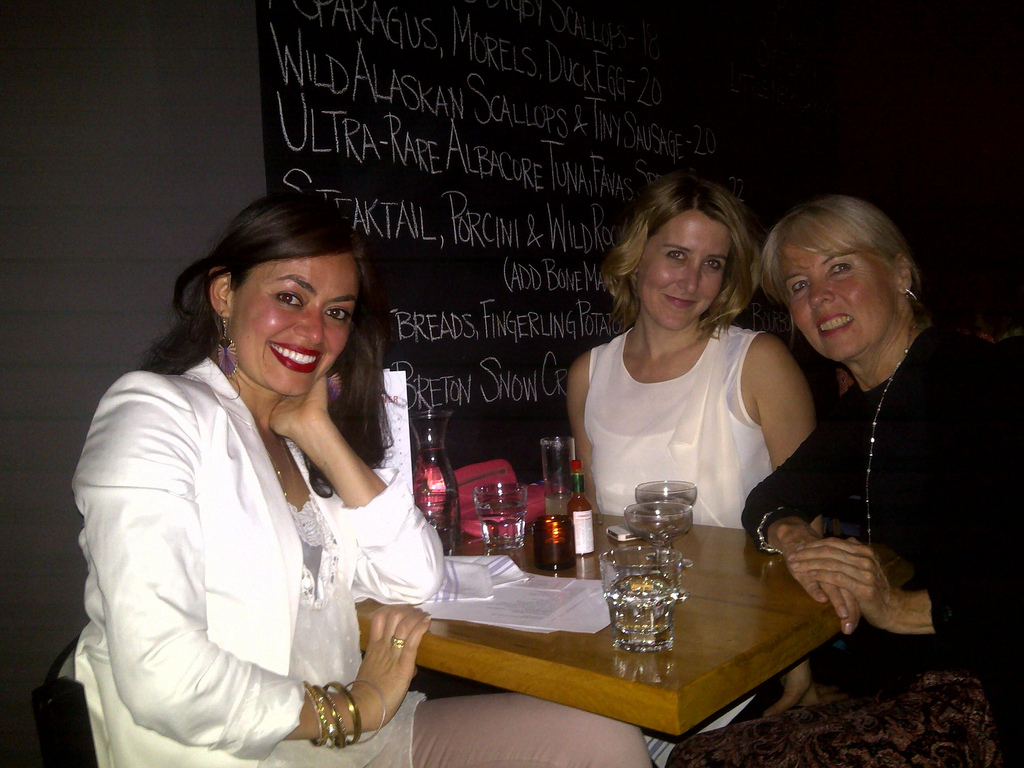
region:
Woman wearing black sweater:
[746, 196, 1021, 766]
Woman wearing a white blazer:
[81, 196, 443, 766]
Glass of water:
[602, 547, 676, 652]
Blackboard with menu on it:
[264, 3, 730, 469]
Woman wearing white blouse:
[566, 177, 792, 528]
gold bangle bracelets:
[307, 679, 384, 747]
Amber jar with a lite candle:
[531, 514, 573, 573]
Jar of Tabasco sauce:
[567, 458, 596, 554]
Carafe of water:
[411, 411, 457, 552]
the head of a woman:
[179, 208, 382, 401]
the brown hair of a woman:
[241, 195, 328, 256]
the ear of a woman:
[201, 270, 249, 327]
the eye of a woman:
[263, 276, 306, 319]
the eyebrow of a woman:
[267, 265, 315, 297]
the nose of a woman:
[295, 322, 337, 349]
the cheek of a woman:
[245, 292, 285, 353]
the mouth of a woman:
[277, 331, 323, 374]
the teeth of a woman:
[294, 349, 313, 366]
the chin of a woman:
[263, 358, 330, 410]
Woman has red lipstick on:
[65, 180, 657, 766]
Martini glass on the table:
[626, 489, 694, 550]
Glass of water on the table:
[595, 547, 688, 652]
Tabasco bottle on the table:
[566, 449, 598, 557]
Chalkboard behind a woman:
[254, 0, 749, 433]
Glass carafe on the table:
[405, 399, 467, 554]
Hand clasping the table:
[348, 593, 438, 734]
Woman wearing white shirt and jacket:
[66, 170, 484, 765]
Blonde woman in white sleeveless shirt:
[555, 146, 803, 539]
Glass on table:
[594, 540, 697, 676]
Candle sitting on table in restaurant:
[528, 508, 576, 585]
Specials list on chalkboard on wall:
[253, 7, 570, 453]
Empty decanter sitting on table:
[397, 397, 467, 576]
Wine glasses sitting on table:
[619, 473, 714, 603]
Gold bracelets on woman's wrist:
[291, 672, 393, 750]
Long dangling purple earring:
[206, 304, 244, 384]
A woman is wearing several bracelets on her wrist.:
[302, 673, 411, 744]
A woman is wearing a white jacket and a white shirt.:
[72, 356, 434, 752]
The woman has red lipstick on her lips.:
[261, 334, 320, 385]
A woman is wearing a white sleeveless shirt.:
[574, 316, 778, 528]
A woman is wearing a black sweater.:
[723, 341, 1002, 703]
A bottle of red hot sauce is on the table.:
[555, 455, 600, 557]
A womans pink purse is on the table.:
[454, 446, 550, 541]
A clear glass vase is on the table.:
[413, 397, 480, 534]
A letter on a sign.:
[471, 352, 501, 407]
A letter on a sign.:
[487, 362, 517, 407]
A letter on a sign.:
[502, 371, 522, 400]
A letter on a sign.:
[518, 371, 537, 400]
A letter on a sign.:
[480, 295, 494, 341]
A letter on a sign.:
[460, 313, 480, 342]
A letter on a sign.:
[443, 308, 469, 340]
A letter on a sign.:
[441, 311, 452, 338]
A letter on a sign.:
[424, 311, 438, 343]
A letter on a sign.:
[413, 302, 430, 337]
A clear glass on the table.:
[582, 538, 690, 656]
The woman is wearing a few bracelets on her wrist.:
[287, 663, 398, 756]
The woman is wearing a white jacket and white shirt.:
[57, 367, 430, 764]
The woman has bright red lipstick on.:
[268, 334, 326, 376]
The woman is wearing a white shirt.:
[527, 325, 781, 531]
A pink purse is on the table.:
[435, 437, 562, 536]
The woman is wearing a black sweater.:
[748, 348, 1021, 674]